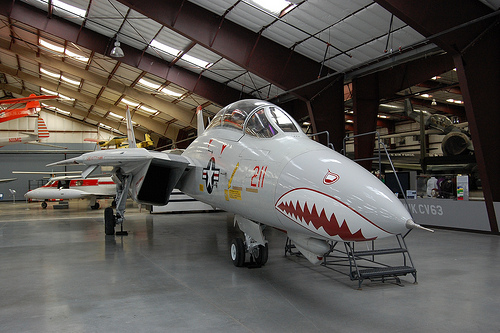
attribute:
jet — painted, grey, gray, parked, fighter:
[46, 100, 435, 267]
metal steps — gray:
[346, 233, 421, 293]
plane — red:
[1, 86, 61, 126]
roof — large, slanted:
[3, 7, 498, 152]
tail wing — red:
[24, 94, 41, 114]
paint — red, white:
[273, 187, 394, 242]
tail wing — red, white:
[31, 112, 48, 137]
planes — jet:
[48, 93, 433, 271]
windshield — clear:
[207, 98, 301, 140]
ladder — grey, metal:
[281, 212, 423, 287]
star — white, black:
[200, 140, 230, 208]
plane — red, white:
[27, 170, 115, 215]